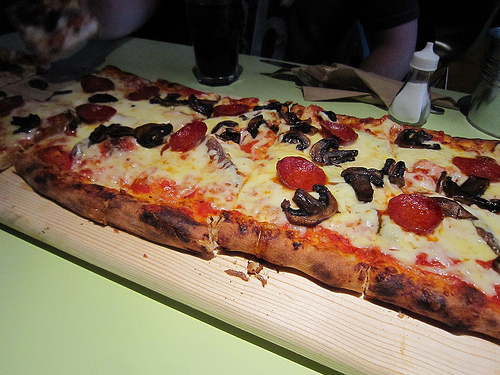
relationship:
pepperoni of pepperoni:
[276, 156, 325, 192] [268, 148, 332, 193]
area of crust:
[134, 199, 209, 238] [22, 143, 499, 352]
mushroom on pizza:
[282, 184, 337, 226] [7, 54, 498, 344]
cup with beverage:
[191, 26, 243, 87] [192, 17, 235, 67]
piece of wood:
[2, 160, 498, 372] [2, 58, 492, 372]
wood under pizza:
[2, 58, 492, 372] [7, 54, 498, 344]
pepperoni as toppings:
[276, 156, 325, 192] [16, 72, 498, 320]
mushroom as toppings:
[282, 184, 337, 226] [16, 72, 498, 320]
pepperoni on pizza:
[272, 148, 340, 198] [7, 54, 498, 344]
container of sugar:
[389, 36, 454, 149] [389, 76, 437, 126]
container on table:
[389, 36, 454, 149] [0, 38, 477, 368]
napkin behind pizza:
[290, 65, 459, 109] [7, 54, 498, 344]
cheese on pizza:
[0, 77, 499, 298] [7, 54, 498, 344]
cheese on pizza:
[391, 231, 418, 261] [7, 54, 498, 344]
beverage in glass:
[192, 17, 236, 76] [180, 1, 250, 95]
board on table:
[2, 59, 499, 366] [0, 38, 477, 368]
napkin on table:
[274, 48, 394, 116] [0, 38, 477, 368]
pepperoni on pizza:
[276, 156, 325, 192] [14, 70, 484, 325]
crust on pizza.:
[84, 206, 484, 294] [35, 89, 485, 315]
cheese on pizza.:
[0, 77, 499, 298] [35, 89, 485, 315]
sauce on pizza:
[150, 196, 385, 285] [35, 83, 482, 314]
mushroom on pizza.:
[272, 189, 351, 228] [35, 89, 485, 315]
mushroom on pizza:
[282, 184, 337, 226] [35, 83, 482, 314]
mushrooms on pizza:
[260, 116, 404, 192] [0, 63, 500, 340]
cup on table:
[200, 26, 244, 84] [0, 38, 477, 368]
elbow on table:
[97, 5, 155, 47] [0, 38, 477, 368]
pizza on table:
[0, 63, 500, 340] [0, 38, 477, 368]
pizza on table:
[0, 63, 500, 340] [57, 35, 476, 372]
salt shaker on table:
[384, 33, 449, 128] [0, 38, 477, 368]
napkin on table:
[290, 65, 459, 109] [0, 38, 477, 368]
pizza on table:
[42, 95, 464, 304] [0, 38, 477, 368]